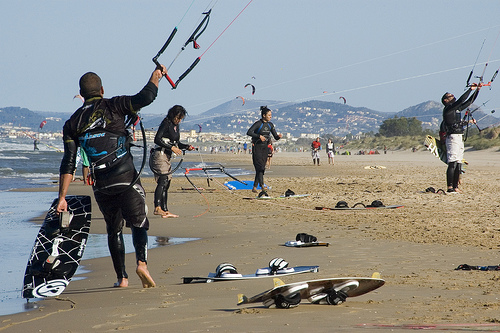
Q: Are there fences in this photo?
A: No, there are no fences.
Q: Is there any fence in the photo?
A: No, there are no fences.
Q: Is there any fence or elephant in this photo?
A: No, there are no fences or elephants.